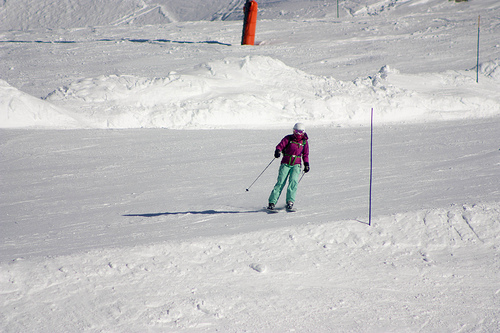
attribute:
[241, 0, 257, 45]
pole — red 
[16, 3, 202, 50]
snow/hillside — white 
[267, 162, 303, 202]
pants — green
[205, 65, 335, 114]
clump — snow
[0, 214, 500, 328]
snow — white 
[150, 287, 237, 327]
snow — white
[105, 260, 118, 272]
clump — snow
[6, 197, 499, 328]
slope — ski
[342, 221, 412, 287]
snow — white 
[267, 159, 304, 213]
pants — green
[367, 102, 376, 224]
pole — long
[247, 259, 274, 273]
clump — snow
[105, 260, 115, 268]
clump — snow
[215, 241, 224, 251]
clump — snow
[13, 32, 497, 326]
slope — ski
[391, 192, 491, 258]
clump — snow